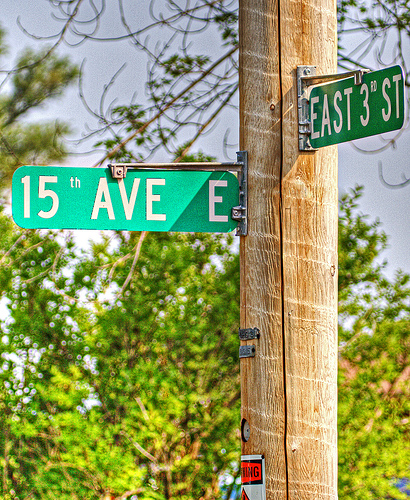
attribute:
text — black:
[239, 463, 262, 482]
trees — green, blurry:
[0, 27, 409, 500]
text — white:
[21, 171, 233, 225]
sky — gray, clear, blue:
[0, 1, 407, 377]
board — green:
[309, 64, 404, 147]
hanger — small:
[294, 61, 369, 84]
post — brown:
[237, 2, 337, 499]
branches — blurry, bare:
[51, 2, 409, 157]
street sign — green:
[303, 64, 405, 151]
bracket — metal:
[107, 160, 248, 181]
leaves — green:
[9, 54, 407, 500]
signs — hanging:
[11, 61, 409, 236]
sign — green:
[10, 164, 242, 235]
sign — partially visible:
[237, 452, 268, 499]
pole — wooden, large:
[237, 2, 339, 499]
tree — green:
[0, 25, 84, 194]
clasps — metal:
[237, 326, 260, 359]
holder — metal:
[106, 156, 251, 236]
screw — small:
[305, 67, 311, 77]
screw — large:
[243, 419, 251, 442]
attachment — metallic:
[295, 64, 367, 153]